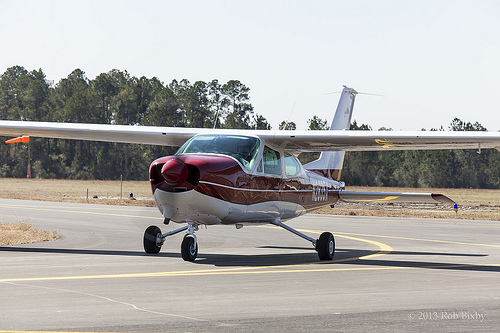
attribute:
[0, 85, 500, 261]
airplane — white, red, here, small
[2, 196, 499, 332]
pavement — gray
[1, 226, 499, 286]
stripe — yellow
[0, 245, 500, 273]
shadow — here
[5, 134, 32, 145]
windsock — orange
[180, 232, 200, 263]
front wheel — small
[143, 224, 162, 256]
right wheel — small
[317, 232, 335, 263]
left wheel — small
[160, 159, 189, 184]
nose — red